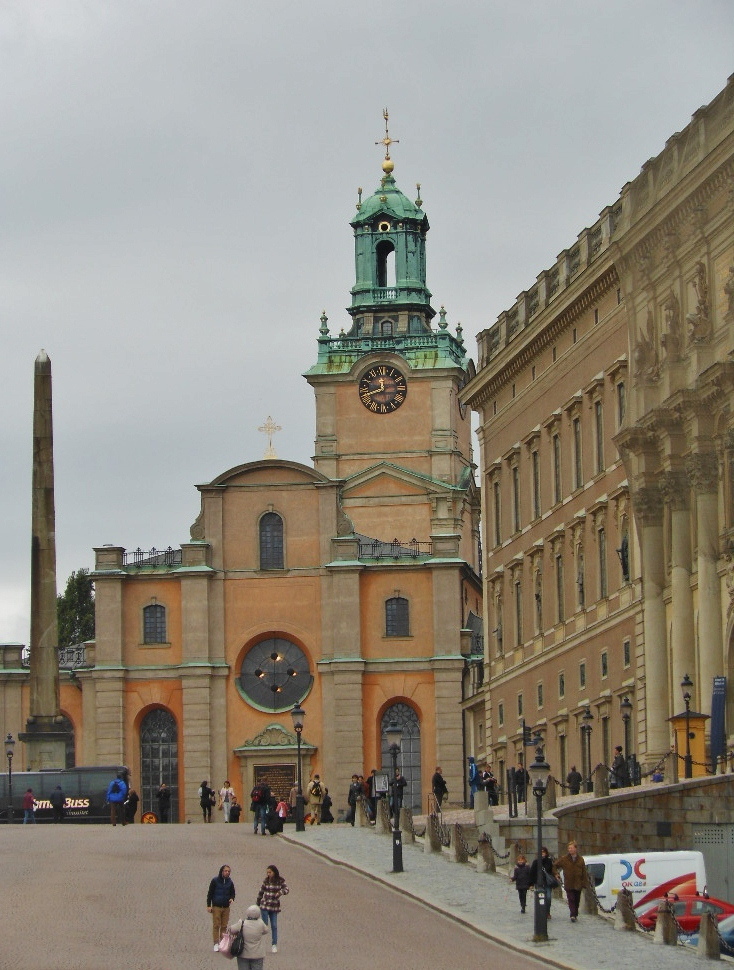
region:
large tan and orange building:
[45, 102, 487, 845]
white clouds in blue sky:
[72, 225, 129, 276]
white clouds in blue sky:
[94, 78, 131, 122]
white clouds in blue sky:
[151, 28, 198, 87]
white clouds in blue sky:
[417, 9, 468, 89]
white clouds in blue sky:
[513, 43, 596, 105]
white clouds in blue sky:
[85, 259, 142, 318]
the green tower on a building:
[314, 110, 473, 367]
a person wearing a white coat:
[230, 910, 269, 961]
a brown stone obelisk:
[20, 347, 68, 772]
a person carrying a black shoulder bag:
[221, 913, 248, 963]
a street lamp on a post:
[611, 695, 639, 783]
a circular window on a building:
[236, 632, 317, 719]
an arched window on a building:
[134, 701, 182, 827]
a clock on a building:
[356, 362, 410, 418]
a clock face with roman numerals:
[357, 363, 408, 417]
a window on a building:
[131, 603, 176, 649]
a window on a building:
[245, 512, 291, 570]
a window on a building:
[391, 586, 417, 637]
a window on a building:
[143, 592, 172, 650]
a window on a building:
[478, 482, 511, 550]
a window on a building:
[488, 594, 501, 644]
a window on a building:
[506, 573, 520, 633]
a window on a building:
[517, 555, 542, 630]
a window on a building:
[537, 546, 566, 621]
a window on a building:
[562, 527, 593, 607]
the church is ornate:
[4, 107, 480, 826]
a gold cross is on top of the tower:
[372, 107, 404, 175]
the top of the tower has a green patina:
[314, 174, 464, 371]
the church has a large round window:
[234, 628, 314, 712]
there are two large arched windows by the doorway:
[122, 678, 422, 820]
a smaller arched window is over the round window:
[252, 502, 287, 575]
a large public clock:
[356, 364, 407, 415]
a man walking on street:
[203, 860, 234, 949]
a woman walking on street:
[256, 862, 286, 952]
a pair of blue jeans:
[260, 909, 276, 944]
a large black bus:
[2, 763, 127, 821]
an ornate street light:
[525, 744, 553, 942]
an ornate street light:
[383, 719, 408, 874]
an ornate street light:
[288, 700, 305, 827]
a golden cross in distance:
[256, 415, 281, 456]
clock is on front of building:
[357, 362, 408, 415]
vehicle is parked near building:
[549, 851, 708, 942]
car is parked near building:
[615, 889, 731, 937]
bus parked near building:
[0, 762, 142, 822]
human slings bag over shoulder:
[215, 902, 273, 968]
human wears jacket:
[250, 863, 290, 948]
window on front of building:
[254, 506, 288, 576]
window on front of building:
[377, 596, 414, 643]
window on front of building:
[139, 605, 168, 650]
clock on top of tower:
[339, 351, 450, 443]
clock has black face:
[350, 353, 417, 420]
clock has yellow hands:
[358, 345, 423, 416]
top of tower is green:
[360, 112, 460, 386]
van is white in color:
[566, 844, 716, 913]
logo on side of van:
[603, 850, 668, 898]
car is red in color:
[633, 867, 729, 940]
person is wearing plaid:
[260, 867, 289, 929]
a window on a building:
[141, 601, 163, 643]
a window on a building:
[257, 516, 281, 563]